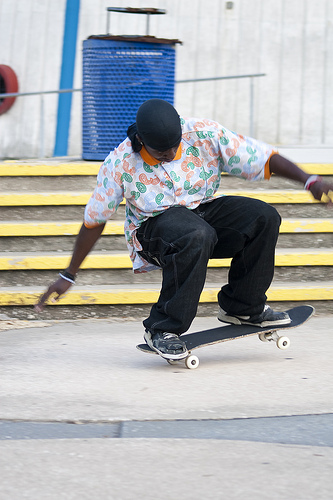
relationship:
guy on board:
[35, 98, 333, 362] [134, 302, 320, 352]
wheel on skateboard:
[275, 336, 291, 353] [138, 291, 314, 358]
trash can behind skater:
[81, 32, 182, 163] [88, 114, 295, 303]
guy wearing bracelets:
[35, 98, 333, 362] [51, 263, 92, 293]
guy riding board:
[35, 98, 333, 362] [134, 302, 316, 368]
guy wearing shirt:
[35, 98, 333, 362] [94, 130, 285, 211]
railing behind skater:
[177, 65, 271, 92] [62, 102, 286, 309]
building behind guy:
[24, 7, 326, 130] [35, 98, 333, 362]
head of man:
[135, 110, 193, 168] [53, 88, 328, 330]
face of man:
[145, 142, 189, 172] [73, 105, 320, 323]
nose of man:
[167, 152, 179, 164] [67, 70, 297, 310]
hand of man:
[30, 277, 88, 308] [75, 80, 294, 328]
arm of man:
[38, 187, 111, 311] [61, 93, 313, 356]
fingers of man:
[36, 290, 68, 308] [43, 74, 296, 317]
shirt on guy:
[81, 135, 275, 228] [35, 98, 333, 362]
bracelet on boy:
[59, 274, 78, 287] [35, 96, 331, 359]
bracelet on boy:
[59, 265, 78, 279] [35, 96, 331, 359]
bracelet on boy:
[305, 174, 321, 190] [35, 96, 331, 359]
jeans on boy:
[137, 194, 285, 334] [35, 96, 331, 359]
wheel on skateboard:
[275, 336, 291, 353] [132, 302, 318, 360]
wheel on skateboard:
[258, 328, 278, 344] [132, 302, 318, 360]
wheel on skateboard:
[184, 352, 200, 370] [132, 302, 318, 360]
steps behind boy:
[0, 158, 332, 304] [35, 96, 331, 359]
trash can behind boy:
[81, 7, 185, 161] [35, 96, 331, 359]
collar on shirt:
[124, 121, 186, 170] [81, 115, 281, 273]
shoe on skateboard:
[216, 305, 294, 331] [137, 299, 316, 369]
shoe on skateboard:
[142, 324, 192, 358] [137, 299, 316, 369]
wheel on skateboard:
[274, 331, 295, 350] [137, 299, 316, 369]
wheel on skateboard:
[258, 328, 278, 344] [137, 299, 316, 369]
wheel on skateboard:
[184, 352, 200, 370] [137, 299, 316, 369]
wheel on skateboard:
[275, 336, 291, 353] [137, 299, 316, 369]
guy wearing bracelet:
[33, 96, 330, 362] [55, 266, 79, 284]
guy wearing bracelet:
[33, 96, 330, 362] [300, 174, 319, 190]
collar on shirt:
[135, 138, 188, 165] [81, 115, 281, 273]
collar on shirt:
[138, 149, 162, 167] [81, 115, 281, 273]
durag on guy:
[126, 98, 182, 150] [35, 98, 333, 362]